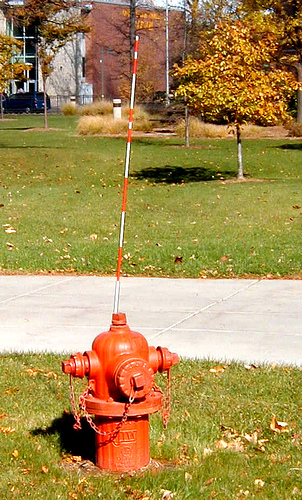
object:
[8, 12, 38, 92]
windows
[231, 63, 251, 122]
leaves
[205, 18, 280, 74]
leaves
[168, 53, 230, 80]
leaves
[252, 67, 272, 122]
leaves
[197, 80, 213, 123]
leaves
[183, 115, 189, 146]
tree trunk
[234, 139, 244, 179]
tree trunk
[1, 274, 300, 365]
sidewalk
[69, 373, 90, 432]
chain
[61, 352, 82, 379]
cap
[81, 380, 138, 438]
chain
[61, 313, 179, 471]
fire hydrant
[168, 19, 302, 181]
colorful foliage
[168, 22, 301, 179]
tree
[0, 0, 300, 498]
outdoors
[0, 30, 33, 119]
tree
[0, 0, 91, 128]
tree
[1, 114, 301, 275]
lawn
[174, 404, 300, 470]
dry leaves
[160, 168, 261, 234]
grass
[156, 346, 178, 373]
cap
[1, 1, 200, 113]
building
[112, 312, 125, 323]
top screw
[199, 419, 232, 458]
leaves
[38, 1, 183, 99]
walls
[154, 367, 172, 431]
chain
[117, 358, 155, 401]
cap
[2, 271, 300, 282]
edge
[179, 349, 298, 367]
edge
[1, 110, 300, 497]
ground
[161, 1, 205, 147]
tree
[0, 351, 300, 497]
grass